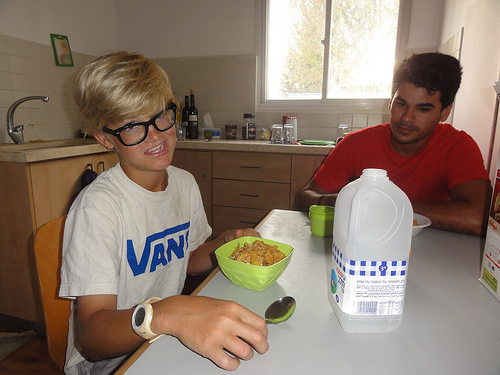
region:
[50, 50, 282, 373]
boy is wearing glasses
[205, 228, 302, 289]
bowl containing breakfast cereal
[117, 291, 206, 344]
white watch on wrist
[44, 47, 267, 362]
boy wearing white shirt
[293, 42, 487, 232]
man wearing red shirt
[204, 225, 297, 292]
the bowl is green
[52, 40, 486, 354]
two people eating breakfast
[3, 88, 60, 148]
faucet is the color silver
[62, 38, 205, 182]
boy has blond hair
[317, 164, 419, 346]
empty milk carton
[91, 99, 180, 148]
the boy is wearing glasses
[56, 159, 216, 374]
The boy is wearing a white shirt.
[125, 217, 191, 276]
The boy's shirt has the word Vans written across it in blue letters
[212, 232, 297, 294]
The boy is eating cereal from a green plastic bowl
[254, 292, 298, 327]
The boy is holding a spoon with his right hand.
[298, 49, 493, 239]
The man is wearing a red shirt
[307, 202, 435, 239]
The man has a green cup and a white bowl in front of him on the table.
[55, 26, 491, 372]
Both the man and the boy are sitting at the table eating their breakfast.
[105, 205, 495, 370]
The man and boy are both sitting at a table eating breakfast.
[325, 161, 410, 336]
An empty milk jug is on the table in front of the boy.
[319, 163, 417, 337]
EMPTY BOTTLE OF MILK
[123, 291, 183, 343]
A BOYS WRIST WATCH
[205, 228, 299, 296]
A BOWL OF CERAL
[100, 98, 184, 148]
A PAIR OF GLASSES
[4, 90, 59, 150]
A KITCHEN FAUCET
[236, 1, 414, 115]
A KITCHEN WINDOW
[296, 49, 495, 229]
A MAN WEARING A RED SHIRT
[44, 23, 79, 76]
A PICTURE ON THE WALL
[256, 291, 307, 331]
A SPOON ON THE TABLE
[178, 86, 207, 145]
TWO WINE BOTTLES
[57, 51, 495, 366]
Boys sitting at table eating cereal.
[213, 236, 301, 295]
Green bowl filled with cereal.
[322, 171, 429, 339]
Jug of milk sitting on table.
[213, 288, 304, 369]
Boy holding a spoon.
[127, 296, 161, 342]
White watch on boy's wrist.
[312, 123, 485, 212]
Boy wearing red shirt.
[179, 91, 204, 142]
Wine bottles sitting on kitchen counter.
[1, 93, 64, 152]
Faucet over kitchen sink.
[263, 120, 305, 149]
Glasses turned down on kitchen counter.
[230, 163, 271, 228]
Handles on kitchen cabinets.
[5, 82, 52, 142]
A water faucet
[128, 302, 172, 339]
A electronic watch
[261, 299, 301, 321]
a spoon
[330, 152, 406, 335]
A gallon of milk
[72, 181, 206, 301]
A white t-shirt with VAN on it.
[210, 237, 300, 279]
Cereals in a green container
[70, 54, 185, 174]
A boy with golden hair and black framed glasses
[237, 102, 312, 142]
Four jars of kitchen stuffs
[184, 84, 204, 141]
A bottle of wine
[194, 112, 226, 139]
a box of tissues